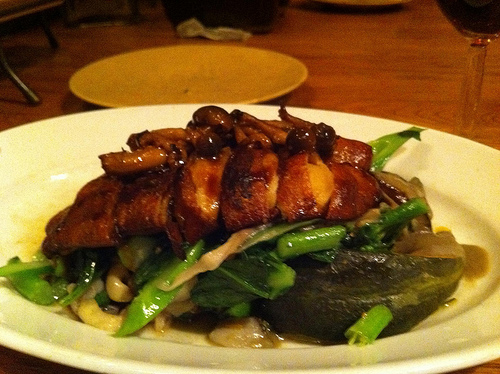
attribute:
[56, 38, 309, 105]
plate — tan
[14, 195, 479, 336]
vegetables — cooked, green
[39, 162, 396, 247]
meat — cooked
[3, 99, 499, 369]
plate — white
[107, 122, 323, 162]
mushrooms — on top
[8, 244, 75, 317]
leaf — green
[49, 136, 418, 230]
pork — braised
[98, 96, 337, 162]
mushrooms — sauteed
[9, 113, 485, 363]
plate — oval, white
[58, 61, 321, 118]
plate — round, brown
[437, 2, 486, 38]
wine — red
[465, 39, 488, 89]
stem — clear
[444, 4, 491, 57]
wine — red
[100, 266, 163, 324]
noodle — bent, white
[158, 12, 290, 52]
plastic — small, twisted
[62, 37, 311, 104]
saucer — brown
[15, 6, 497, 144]
table — wooden